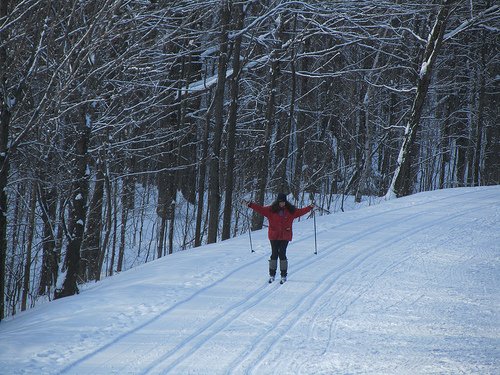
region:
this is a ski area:
[15, 19, 455, 319]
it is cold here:
[11, 51, 432, 315]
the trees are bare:
[35, 46, 262, 192]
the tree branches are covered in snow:
[69, 23, 335, 152]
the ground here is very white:
[109, 294, 398, 366]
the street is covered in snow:
[137, 274, 369, 369]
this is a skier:
[241, 198, 337, 270]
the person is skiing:
[249, 176, 320, 270]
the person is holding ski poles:
[226, 187, 404, 318]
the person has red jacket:
[255, 206, 312, 251]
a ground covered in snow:
[328, 290, 440, 374]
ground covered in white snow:
[332, 282, 437, 369]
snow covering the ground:
[330, 261, 490, 363]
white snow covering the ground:
[314, 253, 476, 356]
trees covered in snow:
[30, 13, 286, 186]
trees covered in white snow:
[44, 29, 256, 209]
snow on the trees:
[59, 31, 176, 123]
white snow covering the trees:
[44, 31, 264, 188]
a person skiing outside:
[211, 171, 347, 316]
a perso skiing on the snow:
[218, 163, 338, 298]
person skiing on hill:
[233, 183, 325, 290]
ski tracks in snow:
[68, 203, 438, 372]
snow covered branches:
[167, 42, 276, 102]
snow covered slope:
[1, 187, 491, 372]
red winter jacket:
[248, 200, 310, 245]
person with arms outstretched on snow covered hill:
[232, 183, 330, 300]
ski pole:
[305, 198, 332, 270]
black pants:
[264, 240, 291, 261]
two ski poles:
[238, 193, 328, 262]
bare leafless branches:
[87, 33, 223, 175]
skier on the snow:
[235, 185, 335, 295]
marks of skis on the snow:
[160, 300, 270, 370]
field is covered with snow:
[9, 185, 493, 374]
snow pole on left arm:
[305, 195, 325, 255]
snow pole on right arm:
[238, 195, 258, 260]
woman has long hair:
[240, 182, 317, 243]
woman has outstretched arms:
[238, 185, 326, 290]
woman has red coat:
[236, 186, 317, 247]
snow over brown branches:
[10, 8, 466, 165]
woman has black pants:
[236, 184, 321, 292]